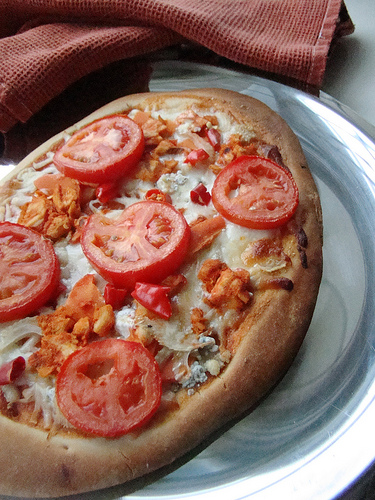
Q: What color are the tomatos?
A: Red.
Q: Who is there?
A: No one.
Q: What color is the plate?
A: Silver.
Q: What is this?
A: Food.